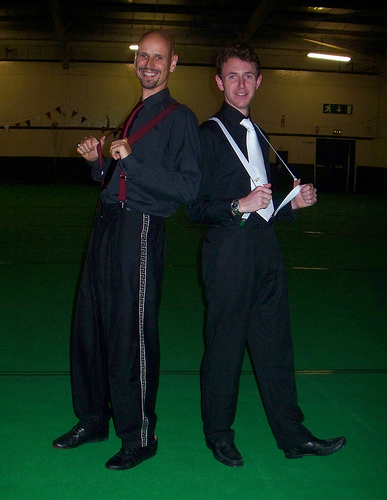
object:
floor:
[1, 183, 387, 500]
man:
[51, 26, 201, 472]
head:
[131, 28, 180, 92]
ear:
[132, 49, 140, 68]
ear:
[170, 51, 178, 74]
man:
[185, 40, 347, 470]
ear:
[214, 75, 224, 91]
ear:
[254, 73, 262, 90]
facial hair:
[135, 61, 169, 90]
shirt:
[85, 86, 203, 219]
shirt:
[182, 102, 298, 223]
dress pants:
[69, 201, 166, 447]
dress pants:
[193, 222, 316, 451]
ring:
[77, 143, 81, 148]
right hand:
[74, 135, 105, 160]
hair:
[213, 40, 260, 79]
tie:
[111, 101, 143, 154]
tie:
[238, 115, 275, 224]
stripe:
[133, 206, 154, 448]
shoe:
[278, 434, 348, 460]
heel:
[285, 449, 306, 459]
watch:
[228, 196, 242, 216]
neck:
[221, 95, 250, 120]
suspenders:
[92, 101, 181, 210]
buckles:
[118, 197, 128, 213]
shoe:
[105, 432, 160, 472]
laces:
[118, 443, 137, 459]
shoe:
[50, 417, 111, 449]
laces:
[68, 421, 84, 437]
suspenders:
[207, 117, 263, 222]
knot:
[239, 117, 254, 135]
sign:
[335, 104, 344, 113]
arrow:
[336, 106, 341, 113]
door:
[313, 134, 358, 193]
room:
[1, 0, 387, 500]